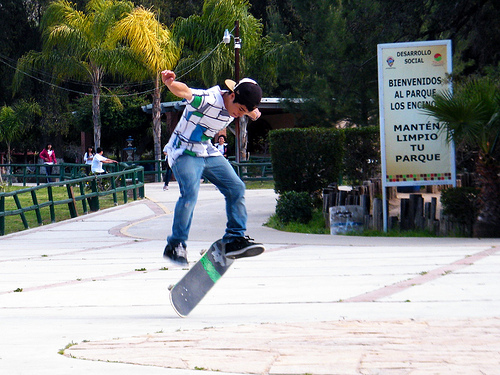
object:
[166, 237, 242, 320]
board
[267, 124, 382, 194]
hedge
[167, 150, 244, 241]
blue jeans.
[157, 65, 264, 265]
boy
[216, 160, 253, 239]
leg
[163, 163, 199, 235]
leg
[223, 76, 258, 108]
baseball cap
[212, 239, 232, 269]
skull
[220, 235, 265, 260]
black shoe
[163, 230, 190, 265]
black shoe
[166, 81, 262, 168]
shirt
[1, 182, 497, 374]
floor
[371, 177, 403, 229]
stand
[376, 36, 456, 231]
board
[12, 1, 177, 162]
trees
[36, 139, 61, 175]
person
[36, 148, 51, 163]
shirt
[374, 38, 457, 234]
sign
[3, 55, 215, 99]
power lines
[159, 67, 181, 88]
raised hand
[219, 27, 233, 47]
light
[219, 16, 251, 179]
pole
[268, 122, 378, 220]
bushes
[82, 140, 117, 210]
person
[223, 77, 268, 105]
snap back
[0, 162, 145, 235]
fence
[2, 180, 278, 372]
cement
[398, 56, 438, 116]
part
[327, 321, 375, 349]
part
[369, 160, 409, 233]
part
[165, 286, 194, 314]
edge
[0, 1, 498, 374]
air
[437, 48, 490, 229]
palm tree